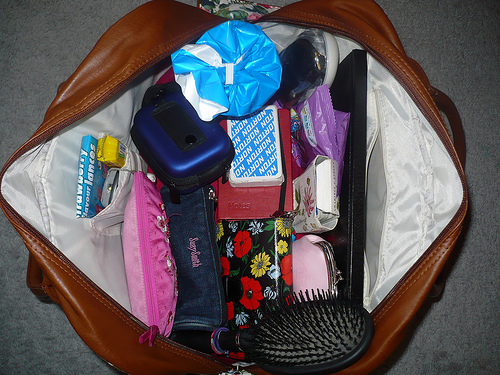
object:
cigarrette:
[291, 154, 342, 235]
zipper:
[249, 14, 471, 346]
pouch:
[120, 167, 180, 345]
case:
[129, 90, 236, 205]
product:
[296, 82, 353, 168]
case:
[159, 182, 229, 333]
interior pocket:
[76, 131, 148, 238]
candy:
[94, 131, 129, 168]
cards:
[225, 104, 286, 188]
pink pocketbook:
[290, 232, 344, 304]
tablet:
[322, 47, 370, 310]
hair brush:
[174, 287, 378, 374]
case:
[210, 217, 296, 364]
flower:
[249, 251, 272, 279]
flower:
[233, 230, 253, 259]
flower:
[238, 276, 264, 311]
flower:
[220, 256, 230, 278]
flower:
[275, 239, 289, 255]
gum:
[74, 134, 112, 221]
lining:
[365, 83, 391, 297]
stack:
[227, 104, 286, 190]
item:
[168, 15, 287, 124]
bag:
[0, 0, 474, 375]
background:
[0, 1, 499, 374]